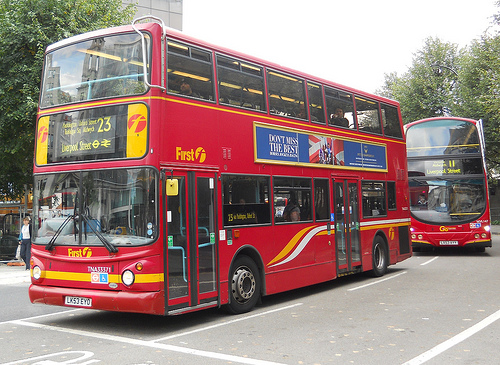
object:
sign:
[242, 114, 392, 175]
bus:
[31, 20, 416, 314]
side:
[156, 26, 416, 301]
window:
[157, 35, 217, 107]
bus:
[398, 113, 495, 250]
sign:
[46, 107, 124, 164]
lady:
[11, 210, 39, 272]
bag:
[10, 240, 24, 262]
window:
[307, 83, 334, 121]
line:
[403, 314, 500, 365]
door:
[323, 167, 387, 297]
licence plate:
[437, 239, 458, 245]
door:
[159, 164, 220, 313]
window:
[353, 94, 383, 134]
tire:
[226, 253, 263, 314]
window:
[265, 67, 310, 124]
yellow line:
[32, 262, 158, 292]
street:
[3, 229, 496, 359]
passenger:
[331, 103, 345, 128]